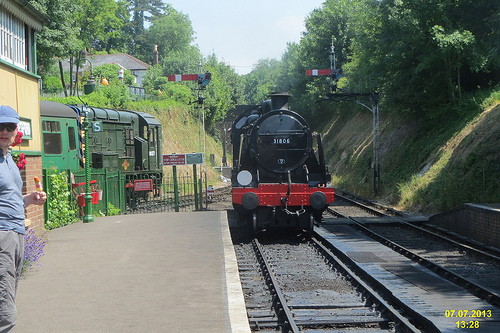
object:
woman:
[1, 104, 26, 333]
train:
[223, 91, 335, 245]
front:
[233, 112, 326, 232]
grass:
[340, 104, 495, 195]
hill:
[347, 72, 499, 203]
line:
[220, 209, 254, 333]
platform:
[24, 209, 236, 332]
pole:
[80, 121, 96, 224]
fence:
[45, 167, 212, 216]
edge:
[83, 207, 229, 219]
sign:
[134, 179, 155, 192]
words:
[136, 182, 150, 189]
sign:
[163, 155, 186, 166]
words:
[161, 155, 185, 164]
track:
[249, 200, 459, 333]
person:
[1, 104, 28, 327]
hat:
[0, 101, 20, 131]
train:
[37, 105, 167, 204]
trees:
[42, 11, 96, 97]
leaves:
[34, 3, 125, 56]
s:
[93, 119, 103, 132]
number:
[271, 137, 293, 145]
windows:
[1, 10, 32, 73]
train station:
[0, 29, 209, 333]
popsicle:
[32, 177, 46, 192]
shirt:
[2, 154, 25, 235]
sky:
[188, 1, 314, 64]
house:
[82, 50, 158, 101]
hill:
[52, 96, 225, 184]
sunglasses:
[0, 123, 19, 133]